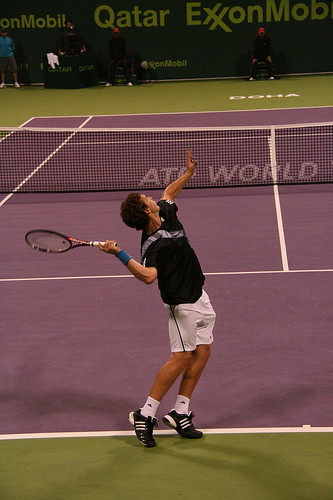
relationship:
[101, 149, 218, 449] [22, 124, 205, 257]
player about to serve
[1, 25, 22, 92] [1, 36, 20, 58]
man wearing t-shirt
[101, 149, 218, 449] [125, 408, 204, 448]
player wearing sneakers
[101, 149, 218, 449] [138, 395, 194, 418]
player wearing socks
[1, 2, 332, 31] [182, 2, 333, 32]
sign indicating exxon mobile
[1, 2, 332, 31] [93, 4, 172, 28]
sign indicating qatar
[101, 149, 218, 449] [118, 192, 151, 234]
man has hair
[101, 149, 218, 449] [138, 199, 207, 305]
player wearing shirt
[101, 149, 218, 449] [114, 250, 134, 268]
player has wrist band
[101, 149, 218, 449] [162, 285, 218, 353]
man has pants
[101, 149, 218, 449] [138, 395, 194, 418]
player wears socks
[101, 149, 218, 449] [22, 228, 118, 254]
player playing racket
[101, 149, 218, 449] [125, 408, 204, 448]
man wearing sneakers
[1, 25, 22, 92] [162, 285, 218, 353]
man dressed in pants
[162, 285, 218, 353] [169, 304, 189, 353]
pants has stripe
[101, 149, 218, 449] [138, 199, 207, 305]
player dressed in shirt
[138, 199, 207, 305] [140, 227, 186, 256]
shirt has accent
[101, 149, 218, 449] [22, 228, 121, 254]
player holding racket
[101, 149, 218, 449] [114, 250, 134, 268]
player wearing wrist band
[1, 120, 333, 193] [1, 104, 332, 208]
net stretched across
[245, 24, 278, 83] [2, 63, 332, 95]
man sitting at end court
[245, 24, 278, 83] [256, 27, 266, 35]
judge wearing cap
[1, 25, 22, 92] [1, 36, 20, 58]
man wearing shirt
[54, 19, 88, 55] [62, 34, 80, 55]
man operating camera